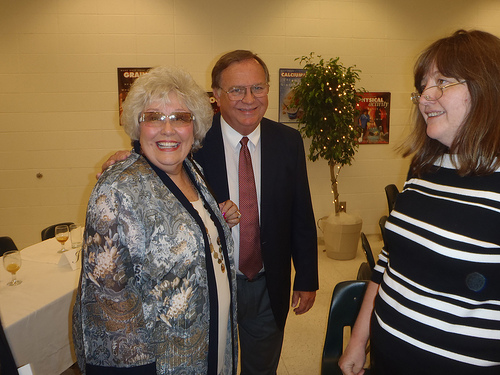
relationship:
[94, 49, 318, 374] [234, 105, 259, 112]
man has smile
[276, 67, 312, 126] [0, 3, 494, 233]
poster on wall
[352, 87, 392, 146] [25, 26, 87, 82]
poster on wall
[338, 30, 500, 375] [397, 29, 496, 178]
lady has brown hair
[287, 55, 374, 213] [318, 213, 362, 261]
tree in pot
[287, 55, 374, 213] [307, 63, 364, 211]
tree in lights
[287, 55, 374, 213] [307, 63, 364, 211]
tree with lights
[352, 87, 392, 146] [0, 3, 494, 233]
poster on wall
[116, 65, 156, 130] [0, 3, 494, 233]
poster on wall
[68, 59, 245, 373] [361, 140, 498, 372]
lady wearing shirt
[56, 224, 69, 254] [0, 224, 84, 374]
wine glass sitting on table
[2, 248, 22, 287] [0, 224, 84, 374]
wine glass sitting on table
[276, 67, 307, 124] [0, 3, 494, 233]
picture posted on wall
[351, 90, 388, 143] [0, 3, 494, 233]
picture posted on wall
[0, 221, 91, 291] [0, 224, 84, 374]
glasses on table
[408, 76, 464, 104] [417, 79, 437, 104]
glasses hanging down on nose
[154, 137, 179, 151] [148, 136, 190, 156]
lipstick on lips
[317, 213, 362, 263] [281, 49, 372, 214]
planter for tree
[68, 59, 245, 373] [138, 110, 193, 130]
lady wears glasses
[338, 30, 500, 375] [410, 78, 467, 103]
lady wears glasses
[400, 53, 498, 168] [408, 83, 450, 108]
lady wears glasses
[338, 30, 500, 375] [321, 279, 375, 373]
lady standing next to chair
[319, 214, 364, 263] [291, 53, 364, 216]
pot for plant